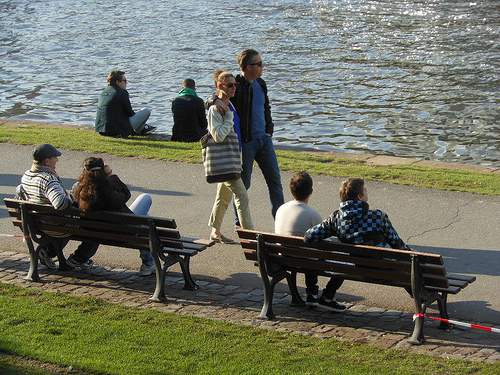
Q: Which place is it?
A: It is a sidewalk.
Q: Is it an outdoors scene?
A: Yes, it is outdoors.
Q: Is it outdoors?
A: Yes, it is outdoors.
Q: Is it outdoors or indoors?
A: It is outdoors.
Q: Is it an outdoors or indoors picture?
A: It is outdoors.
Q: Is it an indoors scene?
A: No, it is outdoors.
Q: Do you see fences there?
A: No, there are no fences.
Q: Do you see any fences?
A: No, there are no fences.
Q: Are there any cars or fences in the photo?
A: No, there are no fences or cars.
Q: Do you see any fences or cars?
A: No, there are no fences or cars.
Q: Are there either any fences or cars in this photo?
A: No, there are no fences or cars.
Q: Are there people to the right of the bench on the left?
A: Yes, there is a person to the right of the bench.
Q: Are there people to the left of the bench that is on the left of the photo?
A: No, the person is to the right of the bench.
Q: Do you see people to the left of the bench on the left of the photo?
A: No, the person is to the right of the bench.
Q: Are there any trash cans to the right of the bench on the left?
A: No, there is a person to the right of the bench.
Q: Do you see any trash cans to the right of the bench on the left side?
A: No, there is a person to the right of the bench.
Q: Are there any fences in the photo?
A: No, there are no fences.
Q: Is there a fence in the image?
A: No, there are no fences.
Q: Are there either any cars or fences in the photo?
A: No, there are no fences or cars.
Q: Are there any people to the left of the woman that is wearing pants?
A: Yes, there is a person to the left of the woman.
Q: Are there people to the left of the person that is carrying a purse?
A: Yes, there is a person to the left of the woman.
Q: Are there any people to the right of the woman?
A: No, the person is to the left of the woman.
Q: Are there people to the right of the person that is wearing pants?
A: No, the person is to the left of the woman.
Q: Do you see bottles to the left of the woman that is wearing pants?
A: No, there is a person to the left of the woman.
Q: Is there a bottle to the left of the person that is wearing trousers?
A: No, there is a person to the left of the woman.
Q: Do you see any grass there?
A: Yes, there is grass.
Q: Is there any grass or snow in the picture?
A: Yes, there is grass.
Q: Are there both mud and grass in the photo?
A: No, there is grass but no mud.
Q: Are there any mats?
A: No, there are no mats.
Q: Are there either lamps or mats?
A: No, there are no mats or lamps.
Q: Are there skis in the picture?
A: No, there are no skis.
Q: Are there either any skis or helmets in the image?
A: No, there are no skis or helmets.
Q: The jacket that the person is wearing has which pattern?
A: The jacket is striped.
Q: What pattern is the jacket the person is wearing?
A: The jacket is striped.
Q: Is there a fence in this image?
A: No, there are no fences.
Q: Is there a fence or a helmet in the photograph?
A: No, there are no fences or helmets.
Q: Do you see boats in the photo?
A: No, there are no boats.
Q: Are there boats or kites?
A: No, there are no boats or kites.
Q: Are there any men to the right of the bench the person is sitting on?
A: Yes, there are men to the right of the bench.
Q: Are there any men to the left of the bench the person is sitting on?
A: No, the men are to the right of the bench.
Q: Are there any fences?
A: No, there are no fences.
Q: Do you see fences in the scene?
A: No, there are no fences.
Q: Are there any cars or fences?
A: No, there are no fences or cars.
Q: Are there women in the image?
A: Yes, there is a woman.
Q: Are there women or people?
A: Yes, there is a woman.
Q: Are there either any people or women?
A: Yes, there is a woman.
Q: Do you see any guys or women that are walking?
A: Yes, the woman is walking.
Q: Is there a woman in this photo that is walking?
A: Yes, there is a woman that is walking.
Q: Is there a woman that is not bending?
A: Yes, there is a woman that is walking.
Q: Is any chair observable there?
A: No, there are no chairs.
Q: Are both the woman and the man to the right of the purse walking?
A: Yes, both the woman and the man are walking.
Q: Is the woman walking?
A: Yes, the woman is walking.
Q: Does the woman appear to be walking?
A: Yes, the woman is walking.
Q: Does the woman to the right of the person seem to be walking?
A: Yes, the woman is walking.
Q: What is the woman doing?
A: The woman is walking.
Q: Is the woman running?
A: No, the woman is walking.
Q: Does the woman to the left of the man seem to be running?
A: No, the woman is walking.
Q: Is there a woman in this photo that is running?
A: No, there is a woman but she is walking.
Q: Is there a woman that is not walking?
A: No, there is a woman but she is walking.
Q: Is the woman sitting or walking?
A: The woman is walking.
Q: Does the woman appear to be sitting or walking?
A: The woman is walking.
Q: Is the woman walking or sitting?
A: The woman is walking.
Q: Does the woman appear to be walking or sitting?
A: The woman is walking.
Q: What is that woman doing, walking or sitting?
A: The woman is walking.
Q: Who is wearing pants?
A: The woman is wearing pants.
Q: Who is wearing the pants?
A: The woman is wearing pants.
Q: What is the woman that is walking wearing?
A: The woman is wearing trousers.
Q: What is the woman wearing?
A: The woman is wearing trousers.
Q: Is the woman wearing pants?
A: Yes, the woman is wearing pants.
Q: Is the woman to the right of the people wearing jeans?
A: No, the woman is wearing pants.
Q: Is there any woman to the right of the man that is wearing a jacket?
A: Yes, there is a woman to the right of the man.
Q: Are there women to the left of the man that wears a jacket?
A: No, the woman is to the right of the man.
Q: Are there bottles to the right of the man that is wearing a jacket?
A: No, there is a woman to the right of the man.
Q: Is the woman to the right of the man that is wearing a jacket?
A: Yes, the woman is to the right of the man.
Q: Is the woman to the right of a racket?
A: No, the woman is to the right of the man.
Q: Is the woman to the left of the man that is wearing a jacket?
A: No, the woman is to the right of the man.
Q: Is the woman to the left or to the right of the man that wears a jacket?
A: The woman is to the right of the man.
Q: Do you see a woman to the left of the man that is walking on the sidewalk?
A: Yes, there is a woman to the left of the man.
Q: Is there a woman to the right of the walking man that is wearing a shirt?
A: No, the woman is to the left of the man.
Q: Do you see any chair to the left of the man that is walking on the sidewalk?
A: No, there is a woman to the left of the man.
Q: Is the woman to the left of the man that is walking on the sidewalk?
A: Yes, the woman is to the left of the man.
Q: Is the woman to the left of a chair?
A: No, the woman is to the left of the man.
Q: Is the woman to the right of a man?
A: No, the woman is to the left of a man.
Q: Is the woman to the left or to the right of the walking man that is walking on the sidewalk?
A: The woman is to the left of the man.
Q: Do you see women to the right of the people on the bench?
A: Yes, there is a woman to the right of the people.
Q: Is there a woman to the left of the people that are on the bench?
A: No, the woman is to the right of the people.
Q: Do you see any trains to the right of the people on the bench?
A: No, there is a woman to the right of the people.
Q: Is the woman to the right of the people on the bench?
A: Yes, the woman is to the right of the people.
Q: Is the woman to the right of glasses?
A: No, the woman is to the right of the people.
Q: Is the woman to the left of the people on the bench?
A: No, the woman is to the right of the people.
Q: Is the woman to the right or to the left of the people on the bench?
A: The woman is to the right of the people.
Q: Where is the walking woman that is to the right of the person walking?
A: The woman is walking on the sidewalk.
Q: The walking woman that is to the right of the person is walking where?
A: The woman is walking on the sidewalk.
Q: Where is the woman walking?
A: The woman is walking on the sidewalk.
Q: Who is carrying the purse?
A: The woman is carrying the purse.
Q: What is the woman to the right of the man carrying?
A: The woman is carrying a purse.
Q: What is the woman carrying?
A: The woman is carrying a purse.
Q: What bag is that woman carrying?
A: The woman is carrying a purse.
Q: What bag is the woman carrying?
A: The woman is carrying a purse.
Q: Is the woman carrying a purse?
A: Yes, the woman is carrying a purse.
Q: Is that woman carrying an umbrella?
A: No, the woman is carrying a purse.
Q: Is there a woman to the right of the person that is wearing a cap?
A: Yes, there is a woman to the right of the person.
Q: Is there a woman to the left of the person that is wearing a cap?
A: No, the woman is to the right of the person.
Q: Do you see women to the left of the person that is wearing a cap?
A: No, the woman is to the right of the person.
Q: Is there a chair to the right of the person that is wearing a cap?
A: No, there is a woman to the right of the person.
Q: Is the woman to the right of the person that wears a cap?
A: Yes, the woman is to the right of the person.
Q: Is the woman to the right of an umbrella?
A: No, the woman is to the right of the person.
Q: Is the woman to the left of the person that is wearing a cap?
A: No, the woman is to the right of the person.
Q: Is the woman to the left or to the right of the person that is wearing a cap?
A: The woman is to the right of the person.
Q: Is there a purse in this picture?
A: Yes, there is a purse.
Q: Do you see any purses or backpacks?
A: Yes, there is a purse.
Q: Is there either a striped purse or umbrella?
A: Yes, there is a striped purse.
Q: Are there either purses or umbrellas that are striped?
A: Yes, the purse is striped.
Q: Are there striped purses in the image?
A: Yes, there is a striped purse.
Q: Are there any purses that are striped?
A: Yes, there is a purse that is striped.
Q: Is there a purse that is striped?
A: Yes, there is a purse that is striped.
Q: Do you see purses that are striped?
A: Yes, there is a purse that is striped.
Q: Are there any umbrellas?
A: No, there are no umbrellas.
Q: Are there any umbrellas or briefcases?
A: No, there are no umbrellas or briefcases.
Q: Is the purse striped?
A: Yes, the purse is striped.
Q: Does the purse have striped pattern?
A: Yes, the purse is striped.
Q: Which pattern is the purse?
A: The purse is striped.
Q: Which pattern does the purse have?
A: The purse has striped pattern.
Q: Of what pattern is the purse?
A: The purse is striped.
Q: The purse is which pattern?
A: The purse is striped.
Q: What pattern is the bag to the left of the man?
A: The purse is striped.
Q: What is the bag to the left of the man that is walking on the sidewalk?
A: The bag is a purse.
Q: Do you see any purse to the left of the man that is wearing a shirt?
A: Yes, there is a purse to the left of the man.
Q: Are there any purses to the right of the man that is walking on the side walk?
A: No, the purse is to the left of the man.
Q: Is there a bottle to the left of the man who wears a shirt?
A: No, there is a purse to the left of the man.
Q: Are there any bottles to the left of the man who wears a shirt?
A: No, there is a purse to the left of the man.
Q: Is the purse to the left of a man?
A: Yes, the purse is to the left of a man.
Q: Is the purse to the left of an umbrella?
A: No, the purse is to the left of a man.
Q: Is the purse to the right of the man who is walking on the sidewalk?
A: No, the purse is to the left of the man.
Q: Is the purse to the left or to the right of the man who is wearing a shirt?
A: The purse is to the left of the man.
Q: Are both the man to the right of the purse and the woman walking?
A: Yes, both the man and the woman are walking.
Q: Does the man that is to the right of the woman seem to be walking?
A: Yes, the man is walking.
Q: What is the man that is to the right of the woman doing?
A: The man is walking.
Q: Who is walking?
A: The man is walking.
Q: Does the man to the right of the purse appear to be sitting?
A: No, the man is walking.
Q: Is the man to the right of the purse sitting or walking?
A: The man is walking.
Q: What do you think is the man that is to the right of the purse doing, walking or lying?
A: The man is walking.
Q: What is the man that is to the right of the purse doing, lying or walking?
A: The man is walking.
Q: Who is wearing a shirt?
A: The man is wearing a shirt.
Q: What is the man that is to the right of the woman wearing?
A: The man is wearing a shirt.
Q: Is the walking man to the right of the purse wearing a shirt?
A: Yes, the man is wearing a shirt.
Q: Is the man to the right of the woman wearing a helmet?
A: No, the man is wearing a shirt.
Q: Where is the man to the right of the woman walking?
A: The man is walking on the sidewalk.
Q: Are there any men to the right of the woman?
A: Yes, there is a man to the right of the woman.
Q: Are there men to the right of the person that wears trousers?
A: Yes, there is a man to the right of the woman.